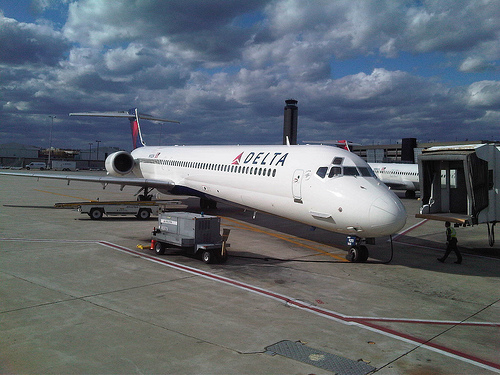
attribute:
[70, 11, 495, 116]
clouds — fluffy 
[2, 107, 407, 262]
plane — large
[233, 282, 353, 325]
lines — white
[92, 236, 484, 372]
line — red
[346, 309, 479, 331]
line — red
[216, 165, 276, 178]
windows — white